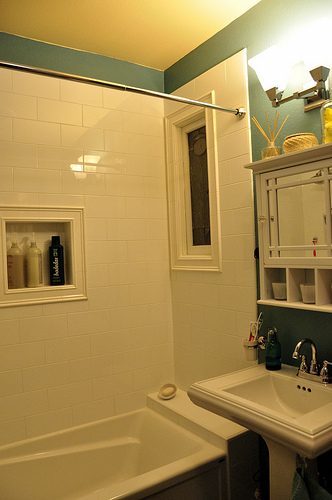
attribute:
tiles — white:
[110, 196, 135, 217]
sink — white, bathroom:
[195, 375, 319, 452]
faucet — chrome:
[284, 338, 315, 371]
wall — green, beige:
[255, 27, 278, 39]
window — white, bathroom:
[179, 127, 213, 243]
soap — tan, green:
[159, 386, 174, 396]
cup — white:
[244, 340, 257, 365]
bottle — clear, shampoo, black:
[251, 119, 287, 159]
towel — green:
[290, 476, 318, 497]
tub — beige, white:
[36, 432, 216, 499]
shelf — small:
[240, 258, 324, 302]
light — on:
[256, 45, 285, 85]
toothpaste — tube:
[239, 318, 265, 350]